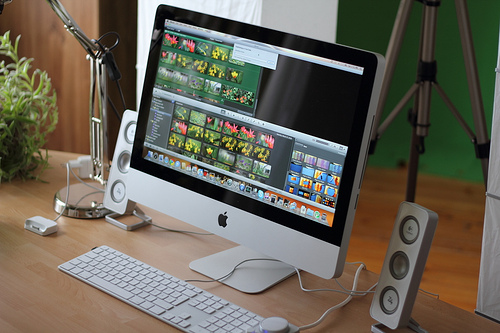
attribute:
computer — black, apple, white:
[119, 5, 399, 303]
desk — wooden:
[2, 143, 497, 332]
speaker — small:
[367, 198, 444, 332]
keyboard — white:
[55, 240, 306, 330]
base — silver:
[49, 173, 111, 224]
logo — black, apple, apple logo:
[211, 206, 237, 234]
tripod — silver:
[364, 0, 492, 215]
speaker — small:
[101, 102, 156, 237]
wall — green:
[336, 1, 500, 185]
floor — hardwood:
[344, 163, 488, 327]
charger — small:
[15, 211, 62, 239]